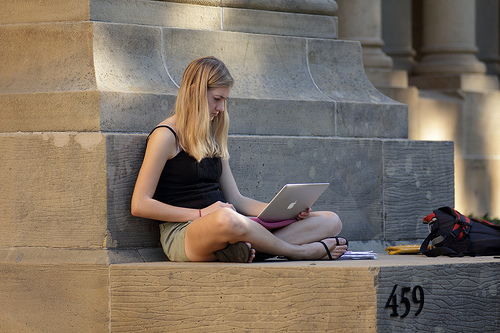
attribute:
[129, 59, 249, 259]
person — blonde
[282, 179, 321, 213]
laptop — apple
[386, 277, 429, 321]
number — 459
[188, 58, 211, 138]
hair — medium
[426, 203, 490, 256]
backpack — sitting, red, black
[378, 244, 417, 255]
envelope — yellow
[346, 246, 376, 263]
paper — white